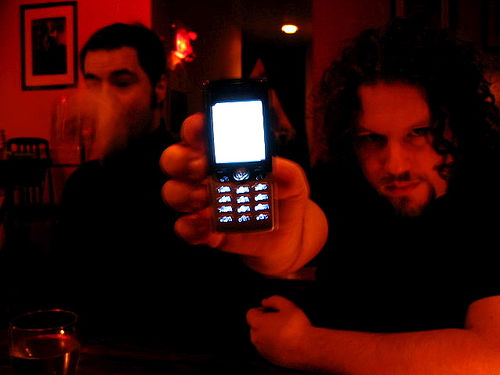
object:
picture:
[0, 0, 500, 375]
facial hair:
[371, 171, 438, 220]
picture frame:
[19, 0, 80, 92]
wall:
[0, 0, 148, 185]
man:
[57, 18, 268, 358]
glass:
[7, 307, 86, 372]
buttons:
[235, 194, 251, 205]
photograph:
[29, 15, 68, 76]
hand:
[245, 292, 318, 371]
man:
[154, 15, 500, 375]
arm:
[308, 293, 500, 373]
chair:
[0, 135, 59, 206]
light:
[280, 22, 300, 35]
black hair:
[305, 17, 499, 209]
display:
[210, 99, 266, 166]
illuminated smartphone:
[199, 75, 280, 238]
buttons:
[215, 184, 232, 194]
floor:
[75, 221, 242, 312]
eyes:
[406, 126, 430, 137]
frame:
[15, 0, 80, 93]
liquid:
[4, 332, 77, 375]